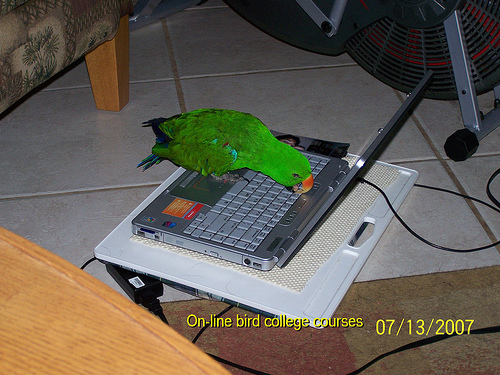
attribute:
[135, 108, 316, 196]
bird — green, parrot, parakeet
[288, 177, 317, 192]
beak — orange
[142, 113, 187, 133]
tail — blue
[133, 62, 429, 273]
laptop — gray, silver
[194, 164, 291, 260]
keyboard — gray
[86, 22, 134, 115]
leg — wooden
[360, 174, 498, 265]
computer cord — black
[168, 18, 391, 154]
tile — white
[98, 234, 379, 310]
tray — white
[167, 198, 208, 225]
label — orange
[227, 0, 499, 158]
exercise bike — grey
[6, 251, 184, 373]
table — brown